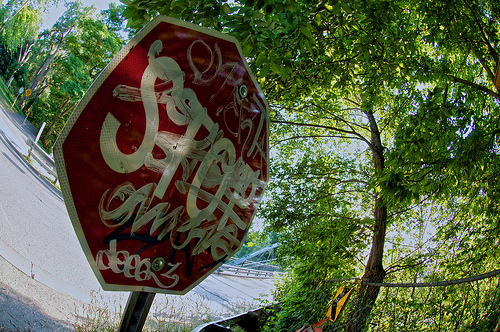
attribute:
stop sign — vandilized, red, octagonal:
[84, 48, 278, 262]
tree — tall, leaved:
[284, 12, 499, 303]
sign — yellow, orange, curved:
[324, 263, 358, 331]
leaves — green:
[272, 15, 334, 68]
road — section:
[24, 174, 94, 319]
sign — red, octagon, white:
[79, 67, 281, 178]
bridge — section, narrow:
[226, 258, 286, 281]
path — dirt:
[4, 283, 49, 322]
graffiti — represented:
[150, 119, 253, 251]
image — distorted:
[22, 19, 499, 299]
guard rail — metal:
[233, 260, 278, 272]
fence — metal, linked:
[377, 277, 492, 331]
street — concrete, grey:
[186, 254, 292, 315]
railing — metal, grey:
[213, 251, 296, 284]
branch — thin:
[269, 114, 353, 139]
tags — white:
[220, 105, 256, 161]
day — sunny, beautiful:
[30, 11, 169, 59]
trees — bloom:
[6, 11, 489, 103]